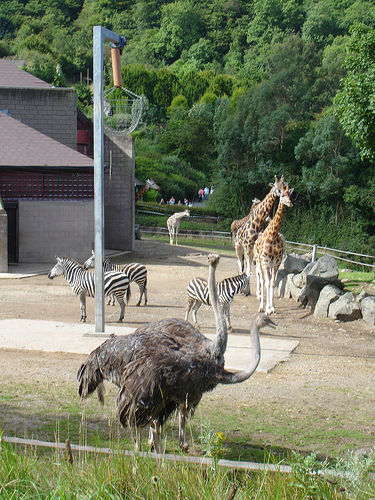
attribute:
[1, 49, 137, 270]
building — large, grey, stoned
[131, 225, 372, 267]
fence — wooden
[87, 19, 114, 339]
pole — tall, steel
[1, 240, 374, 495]
ground — grey, bare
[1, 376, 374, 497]
grass — tall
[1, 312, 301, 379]
base — concrete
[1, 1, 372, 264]
trees — round, beautiful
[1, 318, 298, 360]
pad — concrete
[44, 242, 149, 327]
zebras — stripped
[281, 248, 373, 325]
rocks — huge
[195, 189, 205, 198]
shirt — red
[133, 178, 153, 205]
giraffe — sticking head out 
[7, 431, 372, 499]
fence — wooden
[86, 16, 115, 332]
light post — metal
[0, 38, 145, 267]
building — large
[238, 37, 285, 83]
leaves — green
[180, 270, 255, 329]
zebra — small, black, white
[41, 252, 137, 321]
zebra — white, black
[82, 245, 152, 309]
zebra — black, white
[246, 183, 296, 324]
giraffe — tall, brown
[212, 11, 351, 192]
trees — green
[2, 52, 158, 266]
house — large